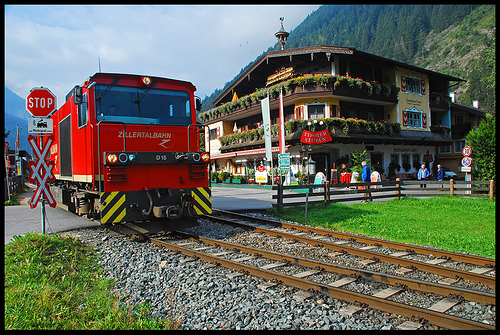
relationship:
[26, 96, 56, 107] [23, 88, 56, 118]
letters on stop sign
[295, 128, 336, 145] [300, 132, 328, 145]
banner with letters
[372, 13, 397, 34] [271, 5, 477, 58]
leaf on plant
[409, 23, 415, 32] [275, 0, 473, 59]
leaf on plant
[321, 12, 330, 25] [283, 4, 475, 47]
leaf on plant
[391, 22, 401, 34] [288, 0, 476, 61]
leaf on plant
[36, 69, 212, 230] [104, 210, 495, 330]
train on tracks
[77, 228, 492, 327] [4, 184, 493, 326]
gravel on ground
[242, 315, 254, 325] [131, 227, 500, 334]
rocks surrounding tracks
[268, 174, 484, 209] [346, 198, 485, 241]
fence bordering area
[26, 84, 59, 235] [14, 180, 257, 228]
sign cautioning people to stop at crossing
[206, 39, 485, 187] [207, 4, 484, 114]
building in front of hill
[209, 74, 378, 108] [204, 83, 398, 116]
plants set above building railing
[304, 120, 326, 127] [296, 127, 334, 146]
lights above banner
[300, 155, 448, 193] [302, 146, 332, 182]
people walking near entrance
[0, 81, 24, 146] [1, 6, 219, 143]
sections in distance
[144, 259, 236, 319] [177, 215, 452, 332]
rocks next to tracks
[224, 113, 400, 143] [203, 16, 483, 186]
flowers on building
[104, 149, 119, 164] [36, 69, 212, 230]
light on train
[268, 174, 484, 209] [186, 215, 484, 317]
fence near tracks